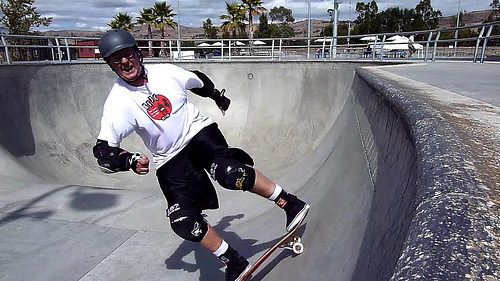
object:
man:
[90, 31, 308, 280]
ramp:
[0, 63, 418, 281]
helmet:
[99, 30, 136, 58]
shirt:
[98, 63, 217, 169]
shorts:
[156, 123, 252, 209]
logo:
[141, 94, 172, 121]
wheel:
[293, 243, 304, 253]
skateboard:
[243, 210, 308, 281]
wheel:
[294, 237, 301, 243]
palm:
[241, 0, 266, 39]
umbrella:
[253, 41, 265, 45]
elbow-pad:
[189, 70, 215, 97]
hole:
[113, 29, 118, 32]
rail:
[3, 21, 499, 63]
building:
[78, 39, 100, 57]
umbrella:
[212, 42, 225, 46]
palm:
[221, 4, 247, 38]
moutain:
[31, 10, 495, 47]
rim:
[355, 69, 500, 281]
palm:
[152, 0, 177, 39]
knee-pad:
[169, 212, 208, 241]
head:
[98, 32, 142, 81]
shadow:
[164, 213, 289, 280]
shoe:
[218, 247, 250, 280]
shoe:
[274, 190, 310, 231]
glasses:
[112, 50, 132, 64]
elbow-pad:
[93, 145, 110, 158]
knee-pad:
[216, 166, 255, 190]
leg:
[156, 168, 237, 263]